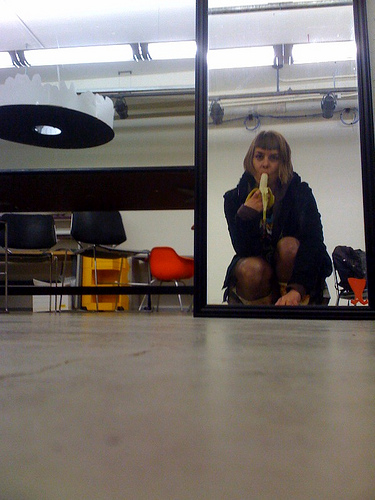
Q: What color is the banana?
A: Yellow.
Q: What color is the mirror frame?
A: Black.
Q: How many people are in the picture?
A: One.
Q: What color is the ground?
A: Light brown.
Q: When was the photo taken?
A: Daytime.